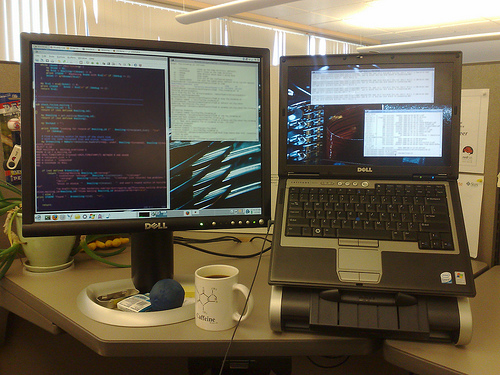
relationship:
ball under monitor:
[149, 283, 182, 308] [20, 32, 272, 287]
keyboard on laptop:
[286, 182, 451, 252] [276, 54, 476, 294]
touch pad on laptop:
[337, 249, 380, 270] [276, 54, 476, 294]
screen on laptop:
[291, 66, 447, 170] [276, 54, 476, 294]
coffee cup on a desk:
[194, 264, 254, 331] [3, 214, 497, 375]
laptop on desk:
[276, 54, 476, 294] [3, 214, 497, 375]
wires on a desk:
[150, 226, 497, 282] [3, 214, 497, 375]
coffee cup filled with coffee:
[194, 264, 254, 331] [206, 269, 230, 282]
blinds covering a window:
[3, 2, 369, 83] [1, 2, 360, 70]